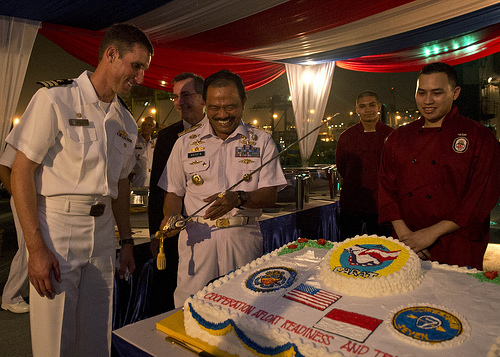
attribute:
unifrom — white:
[23, 100, 130, 343]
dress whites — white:
[13, 75, 138, 355]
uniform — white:
[152, 112, 289, 312]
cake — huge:
[173, 234, 498, 351]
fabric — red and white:
[0, 0, 498, 65]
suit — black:
[147, 119, 194, 240]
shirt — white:
[6, 65, 143, 207]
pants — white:
[13, 188, 128, 350]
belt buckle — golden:
[184, 195, 266, 233]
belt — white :
[38, 176, 135, 218]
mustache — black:
[212, 113, 238, 125]